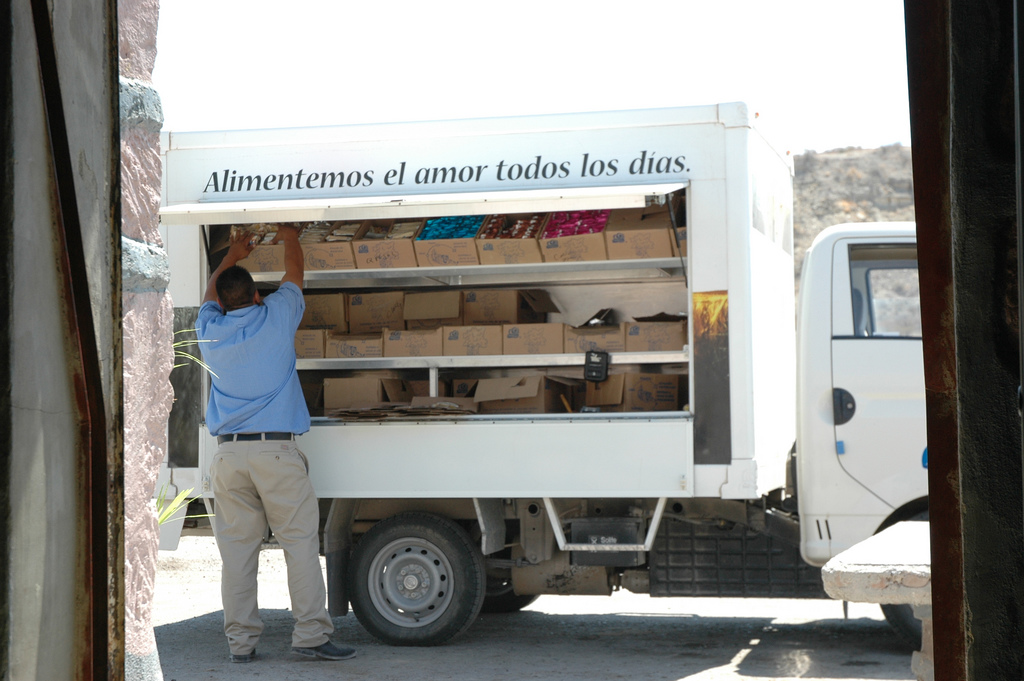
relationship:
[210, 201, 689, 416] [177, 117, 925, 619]
boxes in truck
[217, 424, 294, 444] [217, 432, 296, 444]
belt around belt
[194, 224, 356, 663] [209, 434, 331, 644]
body wears pants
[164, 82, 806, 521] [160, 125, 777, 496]
body of a truck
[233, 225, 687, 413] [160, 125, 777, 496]
boxes in a truck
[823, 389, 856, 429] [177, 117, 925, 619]
handle on a truck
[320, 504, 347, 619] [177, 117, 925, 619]
mudflap on a truck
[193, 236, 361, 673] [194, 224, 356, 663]
hair on a body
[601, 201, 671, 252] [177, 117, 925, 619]
box in a truck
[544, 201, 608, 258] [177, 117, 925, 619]
box in a truck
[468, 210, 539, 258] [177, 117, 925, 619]
box in a truck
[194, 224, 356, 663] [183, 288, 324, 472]
body wearing shirt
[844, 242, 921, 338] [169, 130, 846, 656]
window on truck